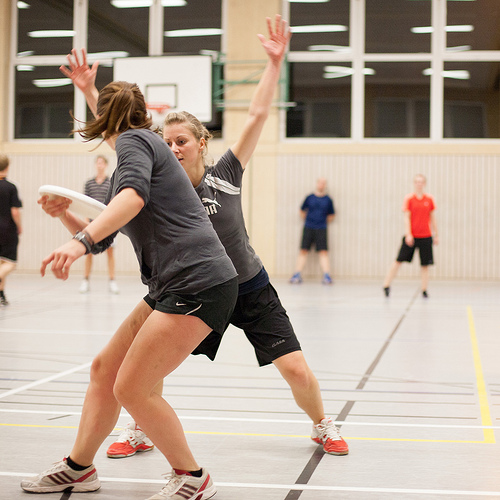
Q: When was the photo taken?
A: Night time.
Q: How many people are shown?
A: Six.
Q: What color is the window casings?
A: White.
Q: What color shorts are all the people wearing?
A: Black.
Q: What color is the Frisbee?
A: White.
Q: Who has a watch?
A: Girl with Frisbee.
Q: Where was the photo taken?
A: In a school gymnasium.